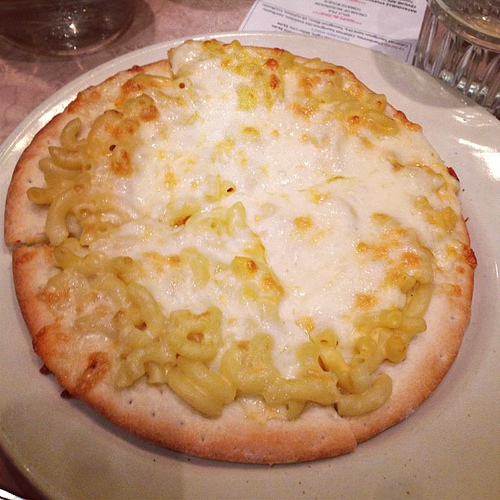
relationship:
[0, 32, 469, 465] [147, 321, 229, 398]
piece with macaroni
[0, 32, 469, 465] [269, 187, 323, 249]
piece with cheese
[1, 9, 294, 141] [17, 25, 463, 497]
tablecloth under a plate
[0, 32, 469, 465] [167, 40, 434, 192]
piece cut into piece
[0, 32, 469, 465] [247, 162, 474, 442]
piece cut into piece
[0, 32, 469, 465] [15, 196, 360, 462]
piece cut into piece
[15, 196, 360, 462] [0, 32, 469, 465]
piece of piece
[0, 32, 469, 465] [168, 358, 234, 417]
piece with macaroni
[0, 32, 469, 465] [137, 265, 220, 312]
piece with cheese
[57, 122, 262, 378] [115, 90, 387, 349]
macaroni and melted cheese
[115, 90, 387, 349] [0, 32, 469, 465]
melted cheese on top of piece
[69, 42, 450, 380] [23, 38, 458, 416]
cheese mixed with macaroni